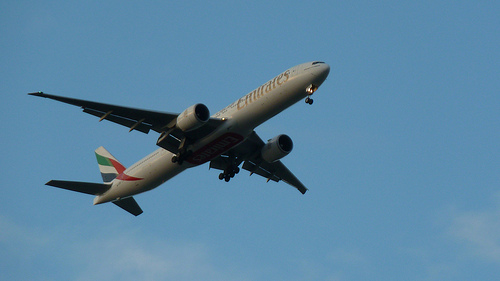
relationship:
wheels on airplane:
[301, 95, 314, 104] [26, 62, 331, 217]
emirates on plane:
[233, 71, 291, 121] [42, 47, 368, 229]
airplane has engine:
[26, 62, 331, 217] [171, 101, 213, 131]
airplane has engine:
[26, 62, 331, 217] [261, 133, 296, 167]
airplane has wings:
[26, 62, 331, 217] [18, 82, 325, 197]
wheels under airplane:
[148, 139, 260, 189] [26, 62, 331, 217]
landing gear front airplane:
[305, 87, 315, 107] [26, 62, 331, 217]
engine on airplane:
[171, 100, 211, 135] [26, 62, 331, 217]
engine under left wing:
[262, 132, 294, 164] [207, 130, 308, 183]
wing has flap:
[27, 91, 227, 154] [82, 107, 153, 134]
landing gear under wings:
[219, 164, 238, 181] [28, 81, 175, 140]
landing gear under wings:
[172, 149, 193, 164] [226, 131, 306, 196]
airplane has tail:
[26, 62, 331, 217] [34, 166, 149, 220]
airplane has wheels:
[26, 62, 331, 217] [296, 76, 320, 108]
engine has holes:
[262, 133, 294, 164] [168, 101, 294, 158]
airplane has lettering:
[26, 62, 331, 217] [234, 67, 296, 112]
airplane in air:
[26, 62, 331, 217] [4, 5, 497, 276]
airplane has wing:
[26, 62, 331, 217] [25, 86, 166, 139]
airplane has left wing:
[26, 62, 331, 217] [221, 130, 309, 195]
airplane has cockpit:
[26, 62, 331, 217] [311, 59, 326, 74]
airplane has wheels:
[26, 59, 331, 219] [169, 147, 194, 167]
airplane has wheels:
[26, 59, 331, 219] [218, 164, 240, 181]